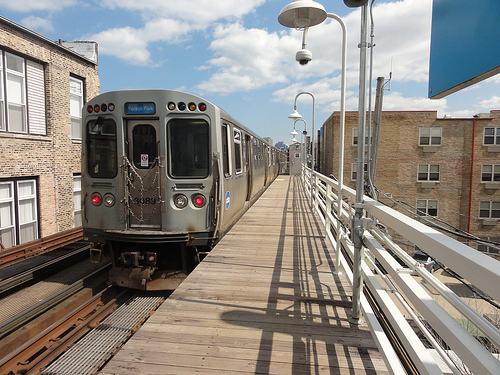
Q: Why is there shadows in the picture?
A: It's a sunny day.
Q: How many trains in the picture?
A: One.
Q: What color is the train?
A: Grey.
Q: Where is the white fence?
A: On the right side of the train.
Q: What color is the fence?
A: White.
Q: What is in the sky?
A: Clouds.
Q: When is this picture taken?
A: During a sunny day.